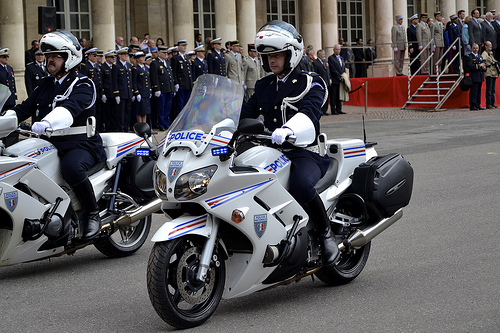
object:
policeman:
[185, 20, 341, 268]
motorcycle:
[130, 72, 416, 330]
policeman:
[9, 31, 105, 253]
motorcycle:
[0, 85, 162, 268]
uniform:
[3, 68, 107, 216]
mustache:
[48, 61, 55, 66]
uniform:
[202, 69, 328, 231]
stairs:
[399, 36, 463, 111]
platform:
[328, 75, 499, 108]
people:
[390, 9, 499, 78]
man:
[327, 43, 347, 115]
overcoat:
[339, 72, 351, 102]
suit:
[328, 53, 347, 112]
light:
[211, 146, 230, 157]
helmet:
[253, 20, 304, 74]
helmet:
[38, 30, 84, 74]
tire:
[145, 235, 225, 328]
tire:
[312, 194, 372, 286]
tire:
[91, 186, 152, 257]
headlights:
[153, 162, 219, 202]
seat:
[313, 157, 338, 194]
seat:
[85, 150, 107, 174]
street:
[0, 116, 498, 331]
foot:
[323, 231, 341, 265]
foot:
[81, 214, 103, 240]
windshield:
[165, 72, 245, 139]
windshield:
[0, 84, 12, 117]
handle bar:
[237, 131, 297, 143]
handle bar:
[16, 122, 53, 134]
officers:
[0, 34, 352, 132]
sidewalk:
[119, 101, 499, 133]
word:
[168, 132, 204, 142]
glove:
[31, 120, 51, 134]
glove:
[271, 127, 294, 145]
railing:
[406, 35, 463, 103]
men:
[462, 40, 486, 111]